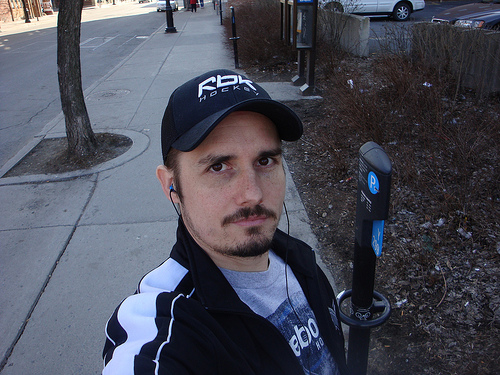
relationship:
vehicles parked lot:
[351, 6, 500, 57] [319, 5, 493, 74]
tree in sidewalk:
[32, 18, 113, 172] [5, 30, 209, 311]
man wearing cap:
[75, 34, 352, 375] [144, 51, 323, 161]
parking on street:
[62, 7, 154, 79] [0, 12, 167, 158]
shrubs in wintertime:
[364, 74, 462, 141] [289, 63, 484, 201]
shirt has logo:
[259, 299, 331, 365] [231, 206, 380, 362]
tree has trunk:
[32, 18, 113, 172] [26, 3, 126, 117]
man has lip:
[75, 34, 352, 375] [212, 200, 293, 239]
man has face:
[75, 34, 352, 375] [177, 125, 304, 265]